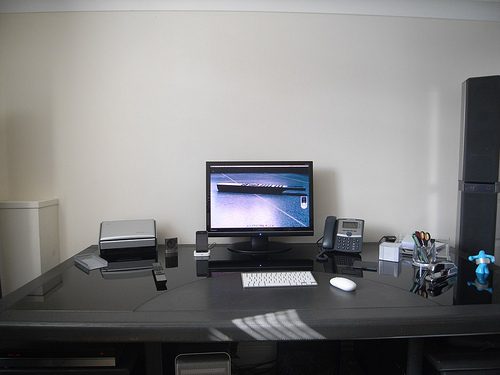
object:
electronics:
[73, 160, 365, 292]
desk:
[0, 240, 500, 341]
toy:
[468, 247, 495, 292]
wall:
[0, 10, 500, 263]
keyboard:
[238, 271, 317, 288]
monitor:
[205, 160, 313, 256]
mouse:
[330, 275, 357, 292]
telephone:
[315, 215, 365, 261]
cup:
[409, 242, 435, 265]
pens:
[409, 231, 432, 262]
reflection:
[209, 308, 325, 341]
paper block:
[378, 242, 402, 262]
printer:
[97, 218, 156, 261]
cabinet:
[0, 199, 59, 295]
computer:
[175, 343, 230, 375]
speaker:
[165, 237, 179, 256]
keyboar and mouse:
[240, 271, 357, 292]